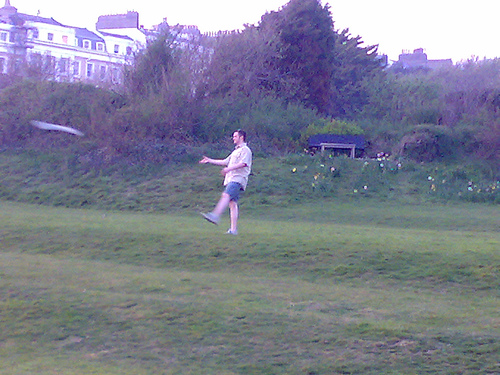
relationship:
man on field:
[198, 130, 251, 235] [1, 197, 499, 371]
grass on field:
[4, 72, 498, 373] [1, 197, 499, 371]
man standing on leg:
[198, 130, 251, 235] [228, 195, 238, 239]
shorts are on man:
[225, 183, 242, 203] [198, 130, 251, 235]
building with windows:
[1, 1, 218, 90] [30, 29, 70, 45]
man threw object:
[198, 130, 251, 235] [32, 121, 81, 138]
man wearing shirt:
[198, 130, 251, 235] [222, 142, 252, 188]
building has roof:
[1, 1, 218, 90] [0, 5, 206, 47]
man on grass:
[198, 130, 251, 235] [4, 72, 498, 373]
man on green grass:
[198, 130, 251, 235] [4, 72, 498, 373]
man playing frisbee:
[198, 130, 251, 235] [26, 119, 251, 236]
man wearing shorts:
[198, 130, 251, 235] [225, 183, 242, 203]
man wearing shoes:
[198, 130, 251, 235] [201, 212, 235, 236]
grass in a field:
[4, 72, 498, 373] [1, 197, 499, 371]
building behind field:
[1, 1, 218, 90] [1, 197, 499, 371]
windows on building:
[30, 29, 70, 45] [1, 1, 218, 90]